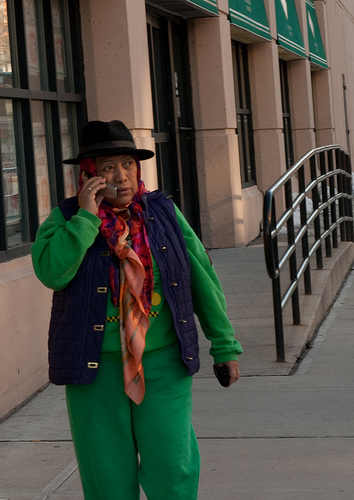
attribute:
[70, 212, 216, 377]
shirt — green